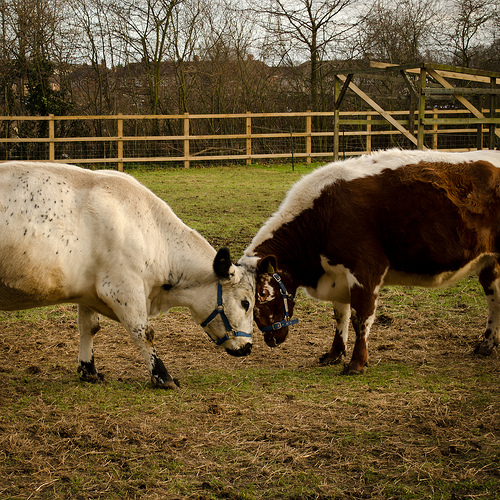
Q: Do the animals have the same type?
A: Yes, all the animals are cows.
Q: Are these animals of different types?
A: No, all the animals are cows.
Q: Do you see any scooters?
A: No, there are no scooters.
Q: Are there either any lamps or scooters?
A: No, there are no scooters or lamps.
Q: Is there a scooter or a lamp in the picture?
A: No, there are no scooters or lamps.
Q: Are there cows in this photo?
A: Yes, there are cows.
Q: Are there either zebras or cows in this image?
A: Yes, there are cows.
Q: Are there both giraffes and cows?
A: No, there are cows but no giraffes.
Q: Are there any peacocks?
A: No, there are no peacocks.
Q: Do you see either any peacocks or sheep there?
A: No, there are no peacocks or sheep.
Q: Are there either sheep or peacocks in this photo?
A: No, there are no peacocks or sheep.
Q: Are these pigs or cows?
A: These are cows.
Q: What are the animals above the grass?
A: The animals are cows.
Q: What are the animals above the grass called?
A: The animals are cows.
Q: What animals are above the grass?
A: The animals are cows.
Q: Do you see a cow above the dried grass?
A: Yes, there are cows above the grass.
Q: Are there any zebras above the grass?
A: No, there are cows above the grass.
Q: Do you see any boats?
A: No, there are no boats.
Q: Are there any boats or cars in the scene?
A: No, there are no boats or cars.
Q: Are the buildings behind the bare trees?
A: Yes, the buildings are behind the trees.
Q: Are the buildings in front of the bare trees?
A: No, the buildings are behind the trees.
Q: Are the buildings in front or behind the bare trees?
A: The buildings are behind the trees.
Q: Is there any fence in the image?
A: Yes, there is a fence.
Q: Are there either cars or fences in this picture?
A: Yes, there is a fence.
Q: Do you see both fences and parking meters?
A: No, there is a fence but no parking meters.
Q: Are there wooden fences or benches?
A: Yes, there is a wood fence.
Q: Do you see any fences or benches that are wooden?
A: Yes, the fence is wooden.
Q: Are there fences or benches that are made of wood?
A: Yes, the fence is made of wood.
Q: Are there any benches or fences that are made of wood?
A: Yes, the fence is made of wood.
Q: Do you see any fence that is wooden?
A: Yes, there is a wood fence.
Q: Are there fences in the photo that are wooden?
A: Yes, there is a fence that is wooden.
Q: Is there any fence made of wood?
A: Yes, there is a fence that is made of wood.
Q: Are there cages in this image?
A: No, there are no cages.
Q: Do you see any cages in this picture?
A: No, there are no cages.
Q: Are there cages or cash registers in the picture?
A: No, there are no cages or cash registers.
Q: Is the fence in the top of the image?
A: Yes, the fence is in the top of the image.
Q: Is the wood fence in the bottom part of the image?
A: No, the fence is in the top of the image.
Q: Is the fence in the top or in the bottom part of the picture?
A: The fence is in the top of the image.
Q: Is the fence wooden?
A: Yes, the fence is wooden.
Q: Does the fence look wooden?
A: Yes, the fence is wooden.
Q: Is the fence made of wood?
A: Yes, the fence is made of wood.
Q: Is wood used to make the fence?
A: Yes, the fence is made of wood.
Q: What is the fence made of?
A: The fence is made of wood.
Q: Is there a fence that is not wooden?
A: No, there is a fence but it is wooden.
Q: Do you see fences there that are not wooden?
A: No, there is a fence but it is wooden.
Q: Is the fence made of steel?
A: No, the fence is made of wood.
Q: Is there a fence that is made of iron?
A: No, there is a fence but it is made of wood.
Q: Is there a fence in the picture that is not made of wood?
A: No, there is a fence but it is made of wood.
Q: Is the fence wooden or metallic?
A: The fence is wooden.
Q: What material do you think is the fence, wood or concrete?
A: The fence is made of wood.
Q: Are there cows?
A: Yes, there is a cow.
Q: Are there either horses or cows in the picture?
A: Yes, there is a cow.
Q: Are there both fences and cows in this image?
A: Yes, there are both a cow and a fence.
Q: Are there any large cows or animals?
A: Yes, there is a large cow.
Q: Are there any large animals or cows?
A: Yes, there is a large cow.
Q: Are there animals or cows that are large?
A: Yes, the cow is large.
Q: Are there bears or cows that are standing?
A: Yes, the cow is standing.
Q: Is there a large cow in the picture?
A: Yes, there is a large cow.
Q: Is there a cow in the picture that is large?
A: Yes, there is a cow that is large.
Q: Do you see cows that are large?
A: Yes, there is a cow that is large.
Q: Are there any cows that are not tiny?
A: Yes, there is a large cow.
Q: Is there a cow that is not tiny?
A: Yes, there is a large cow.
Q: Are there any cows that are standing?
A: Yes, there is a cow that is standing.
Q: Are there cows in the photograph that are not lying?
A: Yes, there is a cow that is standing.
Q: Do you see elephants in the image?
A: No, there are no elephants.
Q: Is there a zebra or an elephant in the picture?
A: No, there are no elephants or zebras.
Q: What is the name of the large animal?
A: The animal is a cow.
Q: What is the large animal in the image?
A: The animal is a cow.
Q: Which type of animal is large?
A: The animal is a cow.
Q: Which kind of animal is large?
A: The animal is a cow.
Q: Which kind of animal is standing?
A: The animal is a cow.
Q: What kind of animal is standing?
A: The animal is a cow.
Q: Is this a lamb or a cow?
A: This is a cow.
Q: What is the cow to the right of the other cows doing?
A: The cow is standing.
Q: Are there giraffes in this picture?
A: No, there are no giraffes.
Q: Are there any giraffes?
A: No, there are no giraffes.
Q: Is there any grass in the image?
A: Yes, there is grass.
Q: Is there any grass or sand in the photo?
A: Yes, there is grass.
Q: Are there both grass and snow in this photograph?
A: No, there is grass but no snow.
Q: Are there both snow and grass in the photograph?
A: No, there is grass but no snow.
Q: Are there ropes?
A: No, there are no ropes.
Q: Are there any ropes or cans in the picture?
A: No, there are no ropes or cans.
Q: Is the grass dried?
A: Yes, the grass is dried.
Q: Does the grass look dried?
A: Yes, the grass is dried.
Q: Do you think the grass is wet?
A: No, the grass is dried.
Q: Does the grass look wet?
A: No, the grass is dried.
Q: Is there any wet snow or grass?
A: No, there is grass but it is dried.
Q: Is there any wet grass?
A: No, there is grass but it is dried.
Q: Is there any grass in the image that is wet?
A: No, there is grass but it is dried.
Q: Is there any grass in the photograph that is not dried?
A: No, there is grass but it is dried.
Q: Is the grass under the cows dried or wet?
A: The grass is dried.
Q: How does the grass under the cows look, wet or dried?
A: The grass is dried.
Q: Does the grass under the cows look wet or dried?
A: The grass is dried.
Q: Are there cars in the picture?
A: No, there are no cars.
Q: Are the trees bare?
A: Yes, the trees are bare.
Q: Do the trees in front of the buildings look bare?
A: Yes, the trees are bare.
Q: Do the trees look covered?
A: No, the trees are bare.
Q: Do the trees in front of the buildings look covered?
A: No, the trees are bare.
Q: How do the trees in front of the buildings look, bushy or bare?
A: The trees are bare.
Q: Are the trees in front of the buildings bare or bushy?
A: The trees are bare.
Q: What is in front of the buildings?
A: The trees are in front of the buildings.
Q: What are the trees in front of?
A: The trees are in front of the buildings.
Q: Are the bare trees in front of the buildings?
A: Yes, the trees are in front of the buildings.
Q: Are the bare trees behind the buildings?
A: No, the trees are in front of the buildings.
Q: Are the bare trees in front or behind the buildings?
A: The trees are in front of the buildings.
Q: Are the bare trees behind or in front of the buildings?
A: The trees are in front of the buildings.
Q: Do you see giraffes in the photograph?
A: No, there are no giraffes.